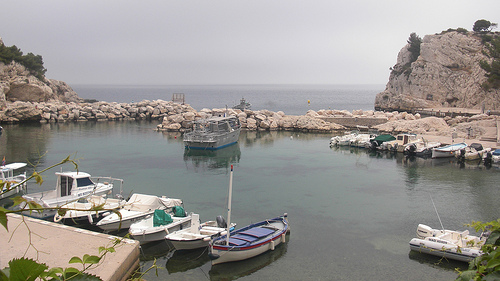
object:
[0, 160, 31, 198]
boats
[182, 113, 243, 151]
boat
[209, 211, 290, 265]
boat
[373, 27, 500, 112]
cliff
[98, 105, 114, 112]
rocks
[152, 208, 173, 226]
tarp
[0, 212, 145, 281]
platform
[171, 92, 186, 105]
stand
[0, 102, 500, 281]
harbor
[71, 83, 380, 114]
ocean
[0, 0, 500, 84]
sky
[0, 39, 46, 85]
bush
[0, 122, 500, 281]
water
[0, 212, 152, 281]
building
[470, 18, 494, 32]
tree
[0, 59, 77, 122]
wall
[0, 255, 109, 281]
ivy